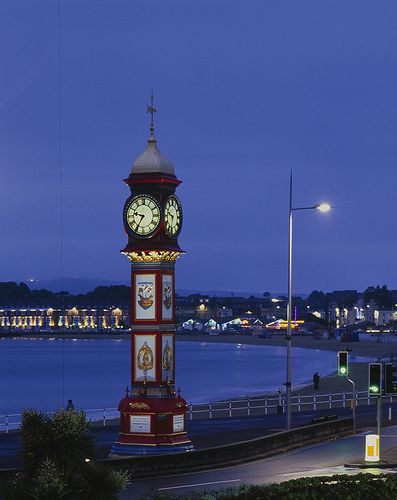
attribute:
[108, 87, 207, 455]
tower — long, red, tall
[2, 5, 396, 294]
sky — huge, open, blue, clear, big, purple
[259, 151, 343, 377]
light — on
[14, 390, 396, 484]
road — grey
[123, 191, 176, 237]
clock — white, on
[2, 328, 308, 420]
water — purple, dark, blue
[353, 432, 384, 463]
box — white, yellow, lit-up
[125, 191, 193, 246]
face — greenish clock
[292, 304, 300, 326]
pole — purple light , background